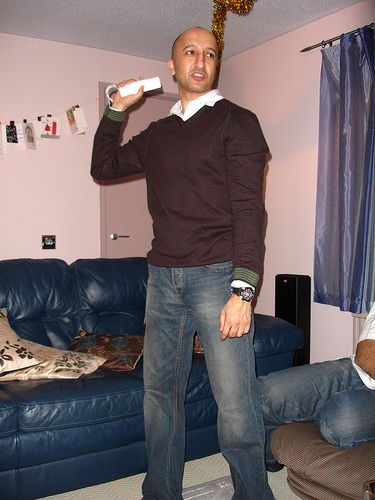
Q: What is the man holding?
A: WII control.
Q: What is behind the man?
A: Blue leather couch.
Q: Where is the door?
A: Behind the couch.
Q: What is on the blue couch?
A: Throw pillows.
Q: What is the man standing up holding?
A: An electronic device.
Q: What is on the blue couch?
A: Pillows.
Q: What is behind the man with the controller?
A: A couch.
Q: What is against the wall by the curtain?
A: A speaker.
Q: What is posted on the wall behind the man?
A: Photographs.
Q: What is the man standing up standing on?
A: A rug.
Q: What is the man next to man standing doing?
A: Sitting down.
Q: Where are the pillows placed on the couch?
A: On the seats.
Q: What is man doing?
A: Playing video game.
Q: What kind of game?
A: Nintendo.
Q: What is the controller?
A: Wiimote.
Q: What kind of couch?
A: Leather.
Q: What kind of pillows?
A: Throw.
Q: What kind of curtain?
A: Sheer.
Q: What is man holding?
A: Controller.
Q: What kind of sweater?
A: V neck.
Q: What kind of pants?
A: Jeans.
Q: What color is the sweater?
A: Brown.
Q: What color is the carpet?
A: White.